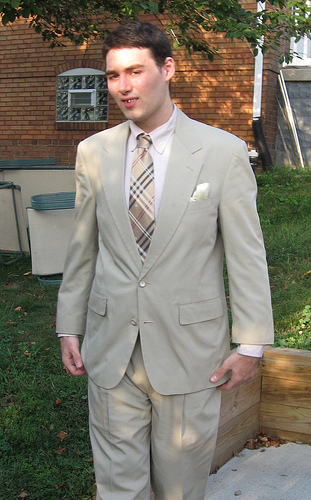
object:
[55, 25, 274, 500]
man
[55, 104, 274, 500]
suit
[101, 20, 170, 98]
his hair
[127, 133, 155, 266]
tie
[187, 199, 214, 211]
pocket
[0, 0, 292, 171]
house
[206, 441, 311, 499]
ground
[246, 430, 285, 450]
leaves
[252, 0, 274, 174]
gutters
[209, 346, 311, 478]
wood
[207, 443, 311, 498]
cement slab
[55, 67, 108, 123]
window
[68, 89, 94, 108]
airconditioner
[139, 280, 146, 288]
buttons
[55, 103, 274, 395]
jacket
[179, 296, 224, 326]
pocket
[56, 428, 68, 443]
leaves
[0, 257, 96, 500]
ground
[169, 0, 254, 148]
wall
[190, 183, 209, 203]
handkerchief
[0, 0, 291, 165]
brick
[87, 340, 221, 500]
pants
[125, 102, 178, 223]
dress shirt